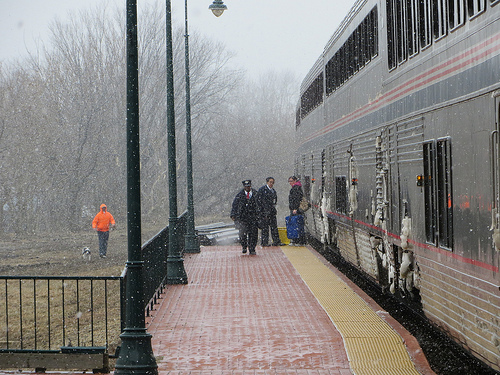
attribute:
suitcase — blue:
[285, 207, 302, 244]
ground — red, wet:
[144, 219, 434, 374]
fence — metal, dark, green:
[2, 267, 140, 357]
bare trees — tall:
[39, 21, 116, 190]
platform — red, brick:
[96, 171, 291, 373]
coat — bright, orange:
[86, 196, 125, 238]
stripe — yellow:
[287, 248, 419, 374]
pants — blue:
[98, 230, 109, 255]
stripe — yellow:
[280, 242, 418, 373]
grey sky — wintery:
[255, 17, 313, 46]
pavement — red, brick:
[142, 237, 432, 373]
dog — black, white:
[78, 244, 93, 261]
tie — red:
[245, 187, 250, 200]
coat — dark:
[230, 188, 264, 227]